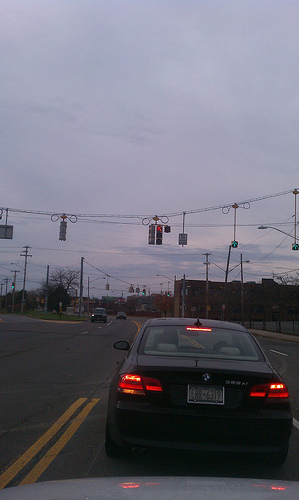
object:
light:
[186, 324, 211, 332]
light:
[155, 222, 163, 246]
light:
[58, 220, 68, 242]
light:
[165, 291, 171, 298]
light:
[11, 281, 15, 290]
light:
[118, 372, 143, 396]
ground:
[0, 316, 299, 500]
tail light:
[268, 381, 288, 399]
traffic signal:
[290, 240, 299, 252]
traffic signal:
[141, 281, 147, 299]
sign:
[177, 232, 187, 245]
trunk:
[134, 353, 273, 445]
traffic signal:
[231, 239, 239, 250]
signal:
[0, 210, 14, 238]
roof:
[144, 316, 247, 333]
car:
[115, 311, 127, 320]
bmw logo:
[199, 371, 211, 384]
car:
[105, 317, 293, 467]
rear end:
[116, 363, 293, 471]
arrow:
[231, 239, 237, 247]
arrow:
[292, 243, 298, 251]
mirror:
[112, 341, 129, 349]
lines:
[0, 393, 87, 483]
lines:
[22, 399, 100, 484]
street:
[1, 314, 298, 487]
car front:
[91, 308, 108, 322]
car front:
[116, 312, 127, 320]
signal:
[230, 204, 239, 249]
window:
[141, 327, 259, 361]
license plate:
[188, 383, 221, 405]